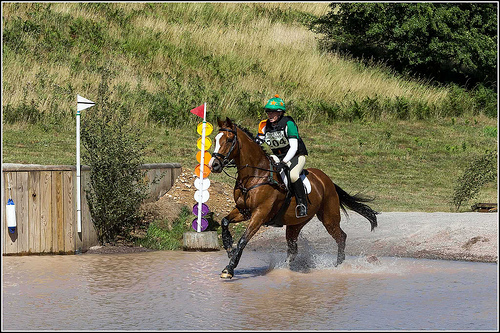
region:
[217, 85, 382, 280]
Person riding horse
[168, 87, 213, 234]
Pole in background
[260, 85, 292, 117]
Green helmet on head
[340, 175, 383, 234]
Tail is long and black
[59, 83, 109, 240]
White flag pole against building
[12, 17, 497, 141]
Grassy knoll in background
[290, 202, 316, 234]
Left foot in stirrup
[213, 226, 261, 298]
Horse's lower legs are black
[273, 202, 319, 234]
Animal's belly is round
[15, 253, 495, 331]
Water within sand bank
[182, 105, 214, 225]
a colorful stack of disks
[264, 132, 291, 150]
a sign on a chest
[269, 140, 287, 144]
black numbers on a white sign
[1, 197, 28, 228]
a blue and white dingy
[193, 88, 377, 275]
a jockey racing his horse through a river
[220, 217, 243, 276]
white black fore legs of the horse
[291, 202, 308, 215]
a leather stirrup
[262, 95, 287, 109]
a green hat with orange accents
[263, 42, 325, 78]
tall wheat grass on a hill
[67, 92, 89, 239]
a flag marking the track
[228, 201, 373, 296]
Horse running through water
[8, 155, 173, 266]
Brown wooden fence beside water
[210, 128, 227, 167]
White stripe on horse's face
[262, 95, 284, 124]
Jockey wearing green helmet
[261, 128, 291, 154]
Jockey's competition number on jersey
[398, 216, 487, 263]
Grey sand beside water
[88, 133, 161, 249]
Small bush next to fence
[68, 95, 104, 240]
White flag on pole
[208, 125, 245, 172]
Black harness on horse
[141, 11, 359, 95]
Beige and green grass on hill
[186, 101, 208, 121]
The red flag on the pole.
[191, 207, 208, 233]
The purple discs on the pole.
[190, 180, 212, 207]
The white discs on the pole.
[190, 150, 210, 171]
The orange discs on the pole.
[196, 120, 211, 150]
The yellow discs on the pole.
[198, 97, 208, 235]
The white pole the colorful discs and red flag are mounted on.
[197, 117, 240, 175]
The head of the horse.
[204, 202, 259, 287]
The front legs of the horse.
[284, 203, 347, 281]
The back legs of the horse.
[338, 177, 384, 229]
The tail of the horse.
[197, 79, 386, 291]
a man riding a brown horse.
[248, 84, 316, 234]
a jockey riding a horse.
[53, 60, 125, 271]
a flag on a wooden fence.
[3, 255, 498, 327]
a body of water under a horse.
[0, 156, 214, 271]
a wooden fence.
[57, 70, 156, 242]
a green plant near a fence.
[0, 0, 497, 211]
a hillside with green grass.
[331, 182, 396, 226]
a tail on a horse.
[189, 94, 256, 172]
a horses head.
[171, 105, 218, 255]
a multi colored flag pole.